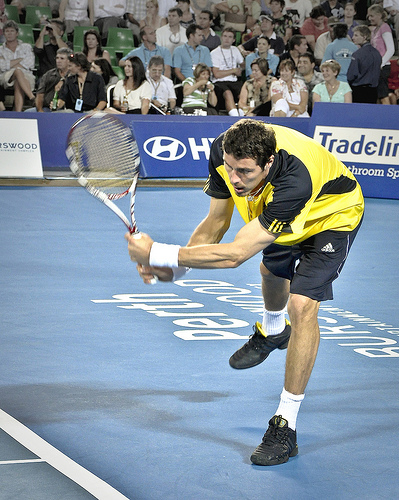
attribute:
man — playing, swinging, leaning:
[127, 110, 366, 467]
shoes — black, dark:
[229, 316, 307, 469]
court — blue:
[2, 184, 397, 499]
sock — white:
[274, 386, 304, 428]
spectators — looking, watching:
[1, 0, 397, 119]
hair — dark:
[222, 118, 278, 168]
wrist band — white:
[146, 237, 183, 268]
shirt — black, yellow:
[201, 120, 369, 243]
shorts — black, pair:
[264, 208, 365, 301]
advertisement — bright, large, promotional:
[313, 103, 398, 201]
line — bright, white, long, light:
[1, 415, 130, 500]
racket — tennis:
[62, 113, 147, 235]